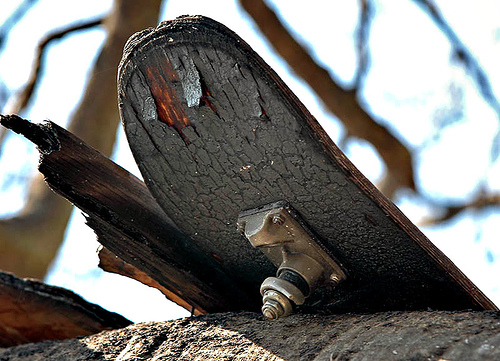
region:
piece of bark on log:
[222, 315, 247, 337]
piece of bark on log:
[303, 339, 318, 353]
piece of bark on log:
[379, 336, 396, 352]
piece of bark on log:
[414, 332, 426, 346]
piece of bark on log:
[428, 336, 456, 353]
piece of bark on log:
[466, 322, 493, 340]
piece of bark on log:
[177, 337, 212, 355]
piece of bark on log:
[231, 322, 249, 340]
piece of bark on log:
[143, 335, 170, 355]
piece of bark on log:
[115, 339, 138, 358]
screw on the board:
[251, 286, 286, 323]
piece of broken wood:
[19, 128, 91, 202]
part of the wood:
[208, 328, 228, 340]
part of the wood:
[328, 332, 349, 346]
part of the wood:
[378, 323, 405, 343]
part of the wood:
[423, 325, 449, 355]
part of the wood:
[101, 333, 134, 360]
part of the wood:
[162, 324, 189, 351]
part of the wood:
[75, 337, 102, 354]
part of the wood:
[203, 324, 248, 357]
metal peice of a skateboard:
[243, 208, 344, 321]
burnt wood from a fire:
[18, 112, 138, 231]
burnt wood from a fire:
[173, 118, 292, 168]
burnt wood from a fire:
[9, 270, 96, 329]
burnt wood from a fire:
[371, 210, 466, 324]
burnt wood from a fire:
[224, 22, 318, 145]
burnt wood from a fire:
[148, 208, 219, 278]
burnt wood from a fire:
[109, 303, 211, 347]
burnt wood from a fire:
[352, 290, 419, 327]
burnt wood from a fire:
[165, 147, 344, 187]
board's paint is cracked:
[110, 34, 390, 331]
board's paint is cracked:
[107, 46, 284, 223]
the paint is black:
[114, 93, 316, 242]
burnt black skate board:
[107, 7, 499, 324]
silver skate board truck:
[231, 195, 361, 326]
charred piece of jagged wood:
[2, 107, 224, 320]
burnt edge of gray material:
[2, 299, 499, 359]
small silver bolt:
[257, 295, 284, 320]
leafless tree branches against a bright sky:
[0, 0, 499, 318]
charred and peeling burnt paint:
[125, 37, 227, 158]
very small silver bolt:
[271, 212, 284, 227]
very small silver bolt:
[327, 270, 342, 283]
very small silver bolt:
[227, 219, 245, 237]